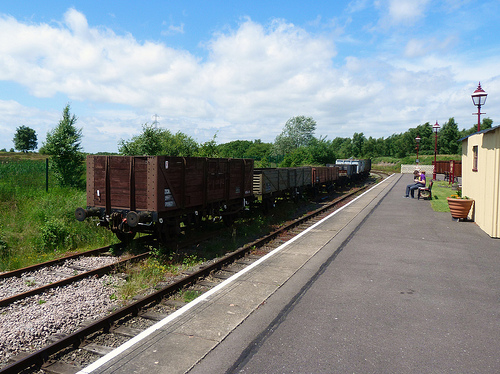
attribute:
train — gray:
[84, 151, 366, 255]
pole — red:
[433, 128, 438, 174]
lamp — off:
[454, 76, 499, 134]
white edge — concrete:
[68, 167, 400, 372]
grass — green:
[424, 179, 461, 211]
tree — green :
[37, 102, 85, 186]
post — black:
[23, 155, 60, 190]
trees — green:
[355, 129, 434, 161]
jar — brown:
[447, 197, 472, 218]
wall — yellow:
[456, 122, 498, 237]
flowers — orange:
[448, 192, 470, 199]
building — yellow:
[449, 135, 499, 219]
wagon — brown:
[78, 143, 258, 261]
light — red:
[468, 77, 489, 111]